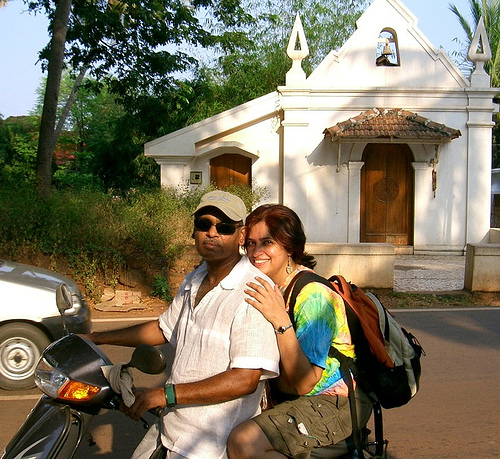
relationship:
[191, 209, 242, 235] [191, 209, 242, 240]
eyes covering eyes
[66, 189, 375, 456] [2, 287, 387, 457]
people on riding moped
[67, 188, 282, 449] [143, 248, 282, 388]
man wearing shirt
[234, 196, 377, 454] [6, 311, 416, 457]
woman riding moped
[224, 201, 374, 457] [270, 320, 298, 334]
woman wearing watch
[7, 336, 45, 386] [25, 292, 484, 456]
silvery cap on a street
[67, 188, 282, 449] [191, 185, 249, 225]
man wearing hat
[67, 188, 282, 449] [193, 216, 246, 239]
man wearing sunglasses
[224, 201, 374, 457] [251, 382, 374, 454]
woman wearing shorts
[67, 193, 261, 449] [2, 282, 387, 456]
man on moped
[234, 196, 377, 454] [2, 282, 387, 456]
woman on moped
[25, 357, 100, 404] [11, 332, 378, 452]
front lights of moped